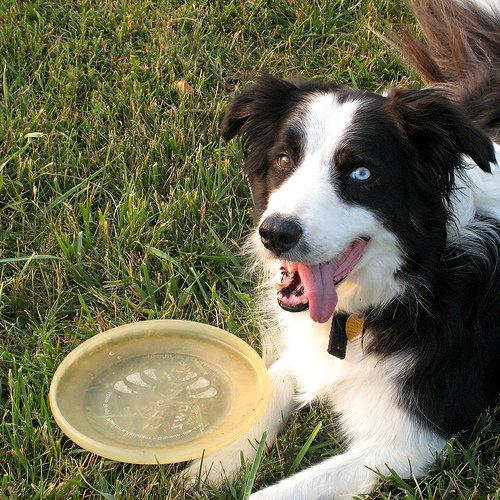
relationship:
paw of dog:
[178, 431, 245, 490] [170, 0, 499, 498]